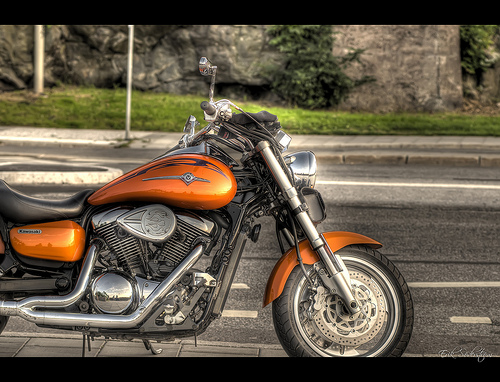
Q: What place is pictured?
A: It is a street.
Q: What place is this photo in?
A: It is at the street.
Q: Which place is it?
A: It is a street.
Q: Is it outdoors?
A: Yes, it is outdoors.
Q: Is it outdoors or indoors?
A: It is outdoors.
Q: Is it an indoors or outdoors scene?
A: It is outdoors.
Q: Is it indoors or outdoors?
A: It is outdoors.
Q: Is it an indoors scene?
A: No, it is outdoors.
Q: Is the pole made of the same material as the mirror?
A: Yes, both the pole and the mirror are made of metal.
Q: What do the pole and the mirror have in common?
A: The material, both the pole and the mirror are metallic.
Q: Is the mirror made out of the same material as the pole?
A: Yes, both the mirror and the pole are made of metal.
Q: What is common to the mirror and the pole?
A: The material, both the mirror and the pole are metallic.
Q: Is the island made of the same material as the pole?
A: No, the island is made of concrete and the pole is made of metal.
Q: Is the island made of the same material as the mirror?
A: No, the island is made of cement and the mirror is made of metal.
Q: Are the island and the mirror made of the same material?
A: No, the island is made of cement and the mirror is made of metal.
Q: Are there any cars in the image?
A: No, there are no cars.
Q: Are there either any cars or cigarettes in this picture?
A: No, there are no cars or cigarettes.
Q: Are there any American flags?
A: No, there are no American flags.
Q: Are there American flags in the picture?
A: No, there are no American flags.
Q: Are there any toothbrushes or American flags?
A: No, there are no American flags or toothbrushes.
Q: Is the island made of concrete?
A: Yes, the island is made of concrete.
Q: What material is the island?
A: The island is made of concrete.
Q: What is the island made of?
A: The island is made of concrete.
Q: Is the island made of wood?
A: No, the island is made of cement.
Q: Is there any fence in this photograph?
A: No, there are no fences.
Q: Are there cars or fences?
A: No, there are no fences or cars.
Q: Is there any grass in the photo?
A: Yes, there is grass.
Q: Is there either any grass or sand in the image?
A: Yes, there is grass.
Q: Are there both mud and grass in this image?
A: No, there is grass but no mud.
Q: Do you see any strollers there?
A: No, there are no strollers.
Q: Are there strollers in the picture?
A: No, there are no strollers.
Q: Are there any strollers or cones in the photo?
A: No, there are no strollers or cones.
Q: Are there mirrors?
A: Yes, there is a mirror.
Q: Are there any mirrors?
A: Yes, there is a mirror.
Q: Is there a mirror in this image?
A: Yes, there is a mirror.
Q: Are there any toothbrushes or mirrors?
A: Yes, there is a mirror.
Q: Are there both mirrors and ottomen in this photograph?
A: No, there is a mirror but no ottomen.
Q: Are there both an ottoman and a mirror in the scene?
A: No, there is a mirror but no ottomen.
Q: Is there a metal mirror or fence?
A: Yes, there is a metal mirror.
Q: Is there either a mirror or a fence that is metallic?
A: Yes, the mirror is metallic.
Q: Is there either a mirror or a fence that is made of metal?
A: Yes, the mirror is made of metal.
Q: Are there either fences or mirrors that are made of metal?
A: Yes, the mirror is made of metal.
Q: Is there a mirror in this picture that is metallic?
A: Yes, there is a metal mirror.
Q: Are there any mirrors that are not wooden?
A: Yes, there is a metallic mirror.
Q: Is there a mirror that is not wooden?
A: Yes, there is a metallic mirror.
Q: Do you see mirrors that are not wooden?
A: Yes, there is a metallic mirror.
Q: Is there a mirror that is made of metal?
A: Yes, there is a mirror that is made of metal.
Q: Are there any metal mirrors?
A: Yes, there is a mirror that is made of metal.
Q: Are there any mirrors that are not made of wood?
A: Yes, there is a mirror that is made of metal.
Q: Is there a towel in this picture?
A: No, there are no towels.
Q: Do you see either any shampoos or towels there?
A: No, there are no towels or shampoos.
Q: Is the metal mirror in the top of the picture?
A: Yes, the mirror is in the top of the image.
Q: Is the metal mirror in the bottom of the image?
A: No, the mirror is in the top of the image.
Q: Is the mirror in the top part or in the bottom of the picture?
A: The mirror is in the top of the image.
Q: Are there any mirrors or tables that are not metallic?
A: No, there is a mirror but it is metallic.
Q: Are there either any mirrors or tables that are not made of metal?
A: No, there is a mirror but it is made of metal.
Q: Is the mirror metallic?
A: Yes, the mirror is metallic.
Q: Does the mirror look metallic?
A: Yes, the mirror is metallic.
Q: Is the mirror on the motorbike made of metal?
A: Yes, the mirror is made of metal.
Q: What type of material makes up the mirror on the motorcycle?
A: The mirror is made of metal.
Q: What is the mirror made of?
A: The mirror is made of metal.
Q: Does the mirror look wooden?
A: No, the mirror is metallic.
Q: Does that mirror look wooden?
A: No, the mirror is metallic.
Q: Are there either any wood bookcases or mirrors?
A: No, there is a mirror but it is metallic.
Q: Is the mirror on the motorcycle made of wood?
A: No, the mirror is made of metal.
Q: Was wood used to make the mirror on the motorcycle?
A: No, the mirror is made of metal.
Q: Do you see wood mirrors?
A: No, there is a mirror but it is made of metal.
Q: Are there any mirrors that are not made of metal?
A: No, there is a mirror but it is made of metal.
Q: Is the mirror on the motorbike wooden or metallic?
A: The mirror is metallic.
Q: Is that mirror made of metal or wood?
A: The mirror is made of metal.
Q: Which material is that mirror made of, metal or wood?
A: The mirror is made of metal.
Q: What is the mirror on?
A: The mirror is on the motorbike.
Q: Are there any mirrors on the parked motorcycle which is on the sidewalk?
A: Yes, there is a mirror on the motorcycle.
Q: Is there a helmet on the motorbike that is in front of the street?
A: No, there is a mirror on the motorcycle.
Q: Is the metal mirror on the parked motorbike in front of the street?
A: Yes, the mirror is on the motorbike.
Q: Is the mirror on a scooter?
A: No, the mirror is on the motorbike.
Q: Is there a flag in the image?
A: No, there are no flags.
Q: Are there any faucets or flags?
A: No, there are no flags or faucets.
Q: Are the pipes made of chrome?
A: Yes, the pipes are made of chrome.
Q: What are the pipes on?
A: The pipes are on the motorcycle.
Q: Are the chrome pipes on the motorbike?
A: Yes, the pipes are on the motorbike.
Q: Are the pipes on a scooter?
A: No, the pipes are on the motorbike.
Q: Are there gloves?
A: Yes, there are gloves.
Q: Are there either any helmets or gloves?
A: Yes, there are gloves.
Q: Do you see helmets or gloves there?
A: Yes, there are gloves.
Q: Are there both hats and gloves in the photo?
A: No, there are gloves but no hats.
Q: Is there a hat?
A: No, there are no hats.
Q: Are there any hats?
A: No, there are no hats.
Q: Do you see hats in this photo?
A: No, there are no hats.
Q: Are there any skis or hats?
A: No, there are no hats or skis.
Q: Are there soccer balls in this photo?
A: No, there are no soccer balls.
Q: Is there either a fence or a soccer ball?
A: No, there are no soccer balls or fences.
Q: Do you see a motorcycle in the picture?
A: Yes, there is a motorcycle.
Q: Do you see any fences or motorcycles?
A: Yes, there is a motorcycle.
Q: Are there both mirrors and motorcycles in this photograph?
A: Yes, there are both a motorcycle and a mirror.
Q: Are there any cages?
A: No, there are no cages.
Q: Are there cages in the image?
A: No, there are no cages.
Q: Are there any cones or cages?
A: No, there are no cages or cones.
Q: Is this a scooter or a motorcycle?
A: This is a motorcycle.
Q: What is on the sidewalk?
A: The motorcycle is on the sidewalk.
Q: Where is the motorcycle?
A: The motorcycle is on the side walk.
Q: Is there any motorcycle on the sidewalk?
A: Yes, there is a motorcycle on the sidewalk.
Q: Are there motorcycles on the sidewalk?
A: Yes, there is a motorcycle on the sidewalk.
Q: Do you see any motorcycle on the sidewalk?
A: Yes, there is a motorcycle on the sidewalk.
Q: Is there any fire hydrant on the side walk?
A: No, there is a motorcycle on the side walk.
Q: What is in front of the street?
A: The motorbike is in front of the street.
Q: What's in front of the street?
A: The motorbike is in front of the street.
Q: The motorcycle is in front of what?
A: The motorcycle is in front of the street.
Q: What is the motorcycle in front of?
A: The motorcycle is in front of the street.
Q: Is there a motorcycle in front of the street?
A: Yes, there is a motorcycle in front of the street.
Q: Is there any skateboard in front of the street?
A: No, there is a motorcycle in front of the street.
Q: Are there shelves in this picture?
A: No, there are no shelves.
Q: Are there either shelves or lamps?
A: No, there are no shelves or lamps.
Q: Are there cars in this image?
A: No, there are no cars.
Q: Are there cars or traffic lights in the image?
A: No, there are no cars or traffic lights.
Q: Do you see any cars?
A: No, there are no cars.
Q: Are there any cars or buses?
A: No, there are no cars or buses.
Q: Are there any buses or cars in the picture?
A: No, there are no cars or buses.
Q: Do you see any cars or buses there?
A: No, there are no cars or buses.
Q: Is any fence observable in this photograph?
A: No, there are no fences.